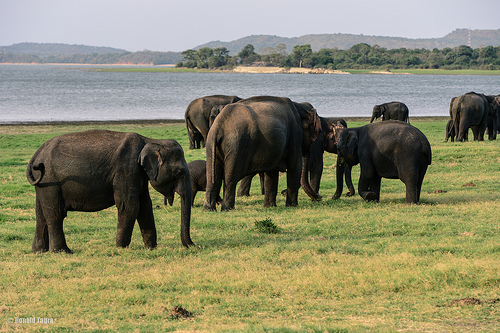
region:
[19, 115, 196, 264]
This is an elephant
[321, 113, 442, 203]
This is an elephant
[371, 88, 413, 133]
This is an elephant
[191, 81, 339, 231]
This is an elephant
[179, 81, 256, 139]
This is an elephant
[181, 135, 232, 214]
This is an elephant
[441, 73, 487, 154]
This is an elephant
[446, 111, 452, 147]
This is an elephant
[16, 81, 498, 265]
A herd of elephant in a savanah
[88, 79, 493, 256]
the elephants are grazing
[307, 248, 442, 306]
the grass is brown incolor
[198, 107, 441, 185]
the elephabts are black in color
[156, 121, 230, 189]
the elphants have with them the calfs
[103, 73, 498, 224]
the elephants are beside ariver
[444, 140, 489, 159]
the grasses are green in color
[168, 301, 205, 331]
there i s aheap of sand in the fild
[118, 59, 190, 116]
the water is colorles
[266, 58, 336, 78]
the land is brown in color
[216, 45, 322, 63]
trees at the end of the river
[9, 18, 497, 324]
animals of the family Elephantidae and the order Proboscidea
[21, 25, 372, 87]
a peninsula jutting out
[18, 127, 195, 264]
an animal of the family Elephantidae and the order Proboscidea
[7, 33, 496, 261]
elephants by a lake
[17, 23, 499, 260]
a group of elephants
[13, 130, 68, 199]
the tail of an elephant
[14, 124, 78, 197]
the tail of an elephant curved upward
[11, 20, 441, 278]
A group of of the family Elephantidae and the order Proboscidea in the grass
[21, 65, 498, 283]
mammals of the family Elephantidae and the order Proboscidea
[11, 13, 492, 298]
a herd of elephants by a lake